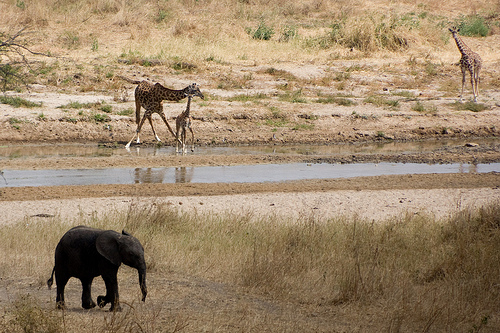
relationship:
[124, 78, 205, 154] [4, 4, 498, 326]
giraffe in wild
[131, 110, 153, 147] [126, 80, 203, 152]
leg of a giraffe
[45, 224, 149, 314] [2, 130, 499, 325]
elephant on savanna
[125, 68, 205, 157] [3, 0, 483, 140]
giraffe on savanna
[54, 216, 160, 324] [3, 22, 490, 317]
elephant roaming in wild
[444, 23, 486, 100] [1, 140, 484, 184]
giraffe standing next to water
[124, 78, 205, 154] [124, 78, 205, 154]
giraffe standing with giraffe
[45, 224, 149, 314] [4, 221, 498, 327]
elephant walking in grass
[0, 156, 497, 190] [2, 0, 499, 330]
water running though valley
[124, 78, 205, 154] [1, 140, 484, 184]
giraffe are near water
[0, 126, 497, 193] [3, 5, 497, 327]
hole in savannah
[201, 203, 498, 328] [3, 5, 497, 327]
grass in savannah